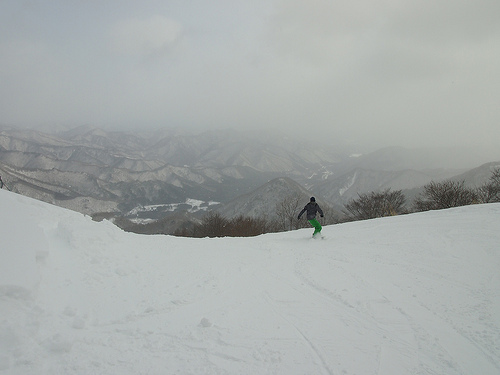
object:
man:
[297, 196, 324, 240]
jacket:
[297, 202, 324, 221]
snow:
[0, 186, 500, 375]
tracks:
[279, 314, 336, 375]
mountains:
[0, 120, 500, 237]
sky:
[2, 0, 499, 147]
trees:
[341, 186, 408, 219]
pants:
[308, 216, 323, 235]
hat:
[309, 196, 315, 202]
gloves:
[297, 215, 300, 220]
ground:
[0, 187, 500, 375]